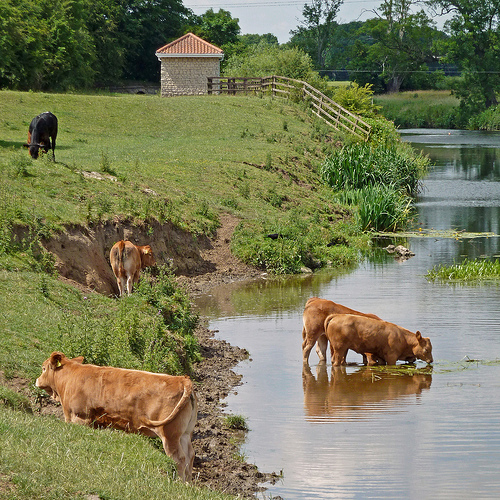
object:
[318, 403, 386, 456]
pond water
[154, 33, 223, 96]
building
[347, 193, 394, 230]
bush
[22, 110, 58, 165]
animal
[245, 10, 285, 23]
sky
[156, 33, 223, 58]
roof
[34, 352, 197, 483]
cow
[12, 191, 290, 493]
land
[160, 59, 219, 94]
wall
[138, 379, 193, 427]
tail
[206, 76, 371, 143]
fence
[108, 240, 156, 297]
cow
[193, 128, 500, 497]
stream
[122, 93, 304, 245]
hill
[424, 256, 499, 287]
grass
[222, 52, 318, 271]
shore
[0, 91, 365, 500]
grass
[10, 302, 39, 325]
patch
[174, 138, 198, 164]
patch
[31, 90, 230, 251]
section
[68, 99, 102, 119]
patch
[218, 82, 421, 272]
edge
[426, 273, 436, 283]
part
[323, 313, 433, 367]
cow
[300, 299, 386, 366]
cow